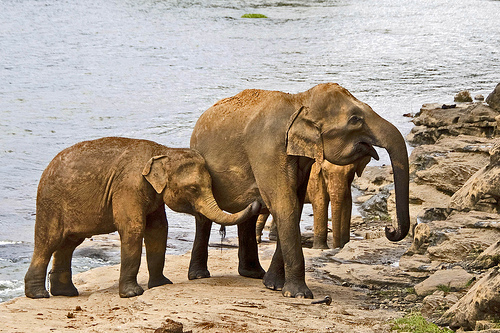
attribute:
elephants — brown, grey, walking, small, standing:
[23, 83, 420, 299]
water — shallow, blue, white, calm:
[1, 5, 500, 213]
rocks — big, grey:
[350, 75, 500, 324]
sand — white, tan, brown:
[16, 234, 422, 331]